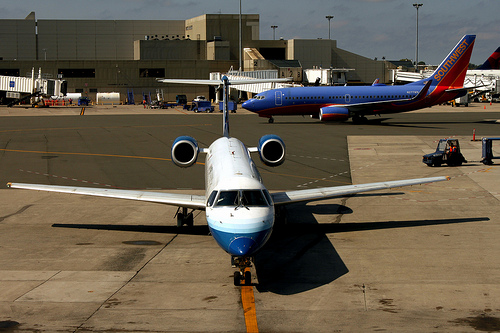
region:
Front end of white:
[222, 237, 259, 259]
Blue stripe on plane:
[216, 222, 268, 231]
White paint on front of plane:
[214, 207, 265, 221]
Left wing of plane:
[6, 168, 204, 236]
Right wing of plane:
[273, 163, 455, 213]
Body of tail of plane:
[209, 87, 244, 139]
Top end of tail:
[142, 58, 295, 99]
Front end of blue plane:
[236, 84, 263, 121]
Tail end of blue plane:
[425, 23, 485, 102]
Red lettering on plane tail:
[429, 29, 473, 84]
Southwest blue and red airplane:
[242, 31, 496, 126]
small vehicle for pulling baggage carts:
[416, 134, 496, 172]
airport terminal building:
[5, 10, 378, 95]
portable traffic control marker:
[462, 125, 482, 145]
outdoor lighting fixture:
[403, 0, 430, 65]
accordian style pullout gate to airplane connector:
[2, 69, 70, 103]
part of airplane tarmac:
[7, 114, 167, 180]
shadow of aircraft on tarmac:
[274, 207, 491, 291]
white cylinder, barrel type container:
[90, 87, 127, 110]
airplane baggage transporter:
[180, 97, 240, 114]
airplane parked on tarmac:
[43, 86, 454, 255]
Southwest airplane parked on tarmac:
[226, 26, 479, 129]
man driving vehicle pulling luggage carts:
[413, 121, 496, 178]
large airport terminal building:
[13, 6, 423, 103]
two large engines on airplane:
[161, 122, 300, 169]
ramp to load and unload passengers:
[6, 63, 81, 113]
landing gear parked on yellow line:
[211, 248, 282, 316]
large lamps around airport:
[263, 3, 448, 58]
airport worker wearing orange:
[131, 91, 158, 117]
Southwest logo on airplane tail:
[396, 28, 482, 104]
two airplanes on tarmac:
[6, 35, 498, 272]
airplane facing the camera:
[8, 68, 453, 265]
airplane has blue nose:
[207, 222, 274, 260]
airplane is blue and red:
[236, 32, 494, 132]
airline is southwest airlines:
[236, 34, 498, 129]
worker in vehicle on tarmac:
[418, 136, 468, 170]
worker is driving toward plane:
[418, 138, 498, 165]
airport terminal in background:
[3, 10, 412, 108]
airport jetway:
[1, 68, 76, 112]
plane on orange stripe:
[232, 258, 261, 329]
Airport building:
[1, 5, 345, 112]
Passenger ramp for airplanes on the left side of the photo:
[1, 62, 84, 117]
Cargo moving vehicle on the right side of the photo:
[400, 127, 495, 193]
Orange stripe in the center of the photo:
[203, 259, 293, 331]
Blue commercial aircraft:
[228, 28, 497, 138]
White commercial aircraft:
[20, 83, 465, 305]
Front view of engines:
[145, 120, 298, 179]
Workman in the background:
[14, 77, 172, 122]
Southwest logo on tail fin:
[413, 28, 495, 95]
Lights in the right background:
[263, 1, 452, 81]